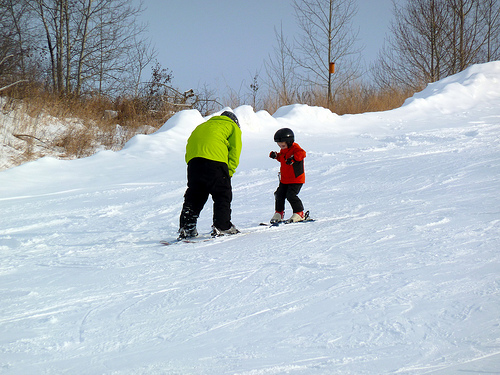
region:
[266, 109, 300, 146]
head of a person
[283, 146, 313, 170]
arm of a person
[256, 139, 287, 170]
arm of a person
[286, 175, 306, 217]
leg of a person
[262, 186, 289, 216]
leg of a person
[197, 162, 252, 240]
leg of a person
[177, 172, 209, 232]
leg of a person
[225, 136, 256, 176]
arm of a person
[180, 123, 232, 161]
back of a person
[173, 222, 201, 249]
leg of a person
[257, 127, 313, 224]
young child on snow skies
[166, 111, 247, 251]
an adult on snow skies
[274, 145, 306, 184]
an orange snow jacket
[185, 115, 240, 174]
a yellow now jacket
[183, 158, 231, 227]
black snow pants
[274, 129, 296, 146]
a black ski helmet for safety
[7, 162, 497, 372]
hillside is covered in snow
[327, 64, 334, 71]
orange can in the tree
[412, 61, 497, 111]
large pile of snow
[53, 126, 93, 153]
a dead bush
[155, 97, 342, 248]
A person and a young child.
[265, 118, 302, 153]
A child's safety helmet.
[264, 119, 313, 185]
Child wearing a red jacket.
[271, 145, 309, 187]
A red long sleeve jacket.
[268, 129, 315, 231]
A child wearing black pants.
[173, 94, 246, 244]
A person wearing black pants.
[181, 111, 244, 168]
Adult wearing a green jacket.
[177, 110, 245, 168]
An adult wearing a long sleeve jacket.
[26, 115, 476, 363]
Tracks in the snow.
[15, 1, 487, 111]
Trees that have no leaves.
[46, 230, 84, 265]
white snow on ground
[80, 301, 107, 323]
white snow on ground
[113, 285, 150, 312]
white snow on ground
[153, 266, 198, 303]
white snow on ground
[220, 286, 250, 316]
white snow on ground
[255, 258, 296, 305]
white snow on ground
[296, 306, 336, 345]
white snow on ground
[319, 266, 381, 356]
white snow on ground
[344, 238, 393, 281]
white snow on ground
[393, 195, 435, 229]
white snow on ground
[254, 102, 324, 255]
child wearing safety helmet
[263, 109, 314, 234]
child wearing orange jacket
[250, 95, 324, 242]
child wearing black winter pants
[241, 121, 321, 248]
child wearing snow skis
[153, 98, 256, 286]
person wearing green jacket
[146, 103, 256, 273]
person wearing insulated pants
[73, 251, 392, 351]
white snow with tracks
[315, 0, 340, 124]
tall tree standing in the background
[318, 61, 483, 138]
beautiful white snowbank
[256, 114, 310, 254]
child wearing snow boots